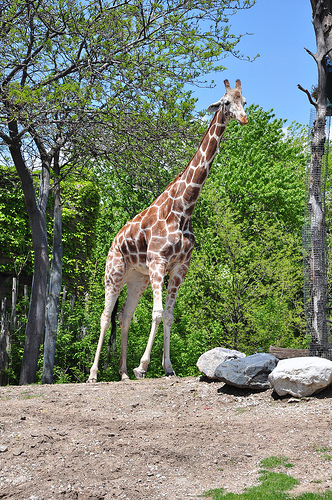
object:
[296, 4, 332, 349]
tree trunk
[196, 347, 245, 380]
rock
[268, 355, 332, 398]
rock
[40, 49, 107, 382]
tree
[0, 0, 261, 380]
tree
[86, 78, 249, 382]
giraffe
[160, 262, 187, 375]
leg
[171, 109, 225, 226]
giraffe's neck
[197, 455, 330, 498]
grass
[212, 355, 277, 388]
rock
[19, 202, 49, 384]
tree trunk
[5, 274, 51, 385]
shadows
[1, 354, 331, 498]
ground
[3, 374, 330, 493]
dirt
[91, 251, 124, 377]
leg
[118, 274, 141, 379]
leg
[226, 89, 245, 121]
face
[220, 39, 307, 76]
sky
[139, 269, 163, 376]
bent leg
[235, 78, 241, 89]
horn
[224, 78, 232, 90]
horn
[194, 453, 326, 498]
grass patch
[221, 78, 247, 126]
head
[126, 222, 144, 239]
spots